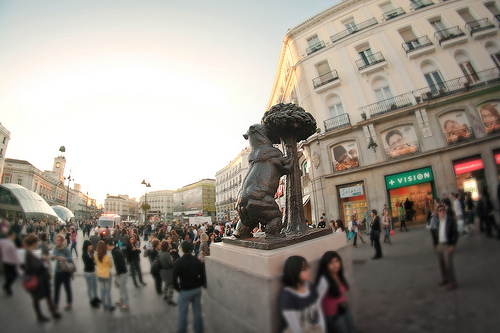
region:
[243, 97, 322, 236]
brown statue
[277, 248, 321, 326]
young woman leaning against wall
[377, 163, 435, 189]
green neon light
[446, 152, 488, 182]
red light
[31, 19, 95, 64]
white clouds in blue sky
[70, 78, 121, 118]
white clouds in blue sky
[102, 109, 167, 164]
white clouds in blue sky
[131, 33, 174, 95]
white clouds in blue sky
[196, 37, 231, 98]
white clouds in blue sky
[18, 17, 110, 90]
white clouds in blue sky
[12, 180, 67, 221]
open umbrella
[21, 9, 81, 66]
white clouds against blue sky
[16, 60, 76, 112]
white clouds against blue sky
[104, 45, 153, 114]
white clouds against blue sky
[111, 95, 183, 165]
white clouds against blue sky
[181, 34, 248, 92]
white clouds against blue sky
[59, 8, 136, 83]
white clouds against blue sky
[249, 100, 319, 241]
statue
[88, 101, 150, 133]
white clouds against blue sky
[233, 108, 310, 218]
dark brown statute in market center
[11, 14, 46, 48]
white clouds in blue sky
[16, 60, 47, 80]
white clouds in blue sky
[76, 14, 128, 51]
white clouds in blue sky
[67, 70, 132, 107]
white clouds in blue sky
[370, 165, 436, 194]
green light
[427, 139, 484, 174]
red light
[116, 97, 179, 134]
white clouds in blue sky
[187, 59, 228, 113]
white clouds in blue sky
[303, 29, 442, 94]
brown building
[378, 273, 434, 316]
The ground is made of cement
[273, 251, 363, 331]
Two women on the side of the statue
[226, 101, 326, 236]
The statue of an animal on a tree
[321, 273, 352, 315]
The woman is wearing a pink shirt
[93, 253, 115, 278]
The woman has on a yellow shirt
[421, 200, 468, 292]
The man standing in the square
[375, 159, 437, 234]
A business in the side of the building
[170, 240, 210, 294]
The man is wearing a black sweater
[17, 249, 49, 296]
The woman is wearing a handbag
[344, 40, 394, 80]
The balcony of an apartment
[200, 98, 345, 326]
bronze statue on elevated stone platform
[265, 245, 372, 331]
two people leaning on elevated stone statue platform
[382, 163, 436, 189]
green sign on front of store front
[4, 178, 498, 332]
crowd of people walking on marketplace walkway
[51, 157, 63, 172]
clock on stone tower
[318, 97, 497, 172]
portraits of faces on front of stone building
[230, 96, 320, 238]
hippopatomause hugging tree in form of bronze statue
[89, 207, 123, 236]
white truck on side of walkwau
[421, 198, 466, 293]
person in black jacket standing alone walkway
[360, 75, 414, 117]
window and balcony on front of building